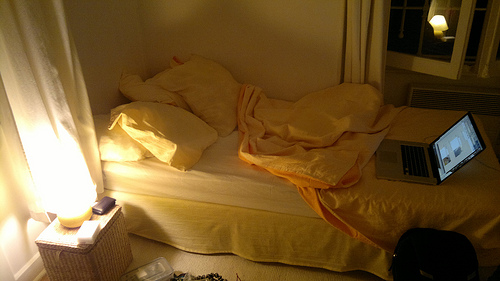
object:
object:
[389, 227, 479, 281]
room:
[0, 0, 500, 281]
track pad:
[378, 149, 398, 164]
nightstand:
[34, 202, 132, 281]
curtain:
[342, 0, 386, 94]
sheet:
[98, 128, 321, 220]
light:
[425, 14, 448, 33]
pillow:
[106, 99, 217, 174]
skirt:
[100, 187, 393, 281]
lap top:
[374, 112, 484, 187]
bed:
[97, 97, 499, 281]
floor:
[42, 232, 499, 281]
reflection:
[418, 0, 461, 63]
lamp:
[23, 162, 95, 231]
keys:
[405, 172, 411, 177]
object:
[88, 195, 115, 216]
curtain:
[0, 0, 104, 217]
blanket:
[234, 81, 500, 269]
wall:
[136, 0, 346, 104]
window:
[383, 0, 477, 81]